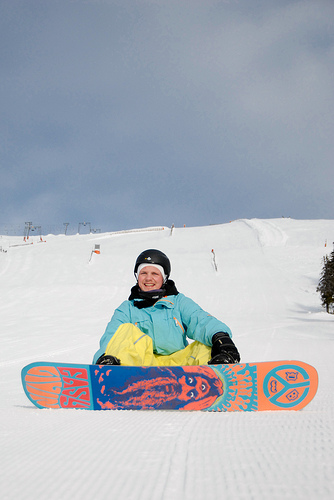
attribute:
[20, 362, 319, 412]
snowboard — painted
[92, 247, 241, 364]
man — sitting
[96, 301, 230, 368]
coat — light blue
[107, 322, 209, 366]
snowpants — yellow, baggy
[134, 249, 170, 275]
helmet — black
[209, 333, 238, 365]
glove — black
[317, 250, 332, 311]
tree — large, green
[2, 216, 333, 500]
hillside — snowy, large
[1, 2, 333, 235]
sky — hazy, blue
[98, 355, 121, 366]
boots — basic, black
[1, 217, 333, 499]
snow — white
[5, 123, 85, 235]
clouds — white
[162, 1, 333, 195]
clouds — white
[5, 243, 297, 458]
snow — white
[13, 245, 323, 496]
snow — white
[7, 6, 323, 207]
sky — blue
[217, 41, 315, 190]
clouds — white